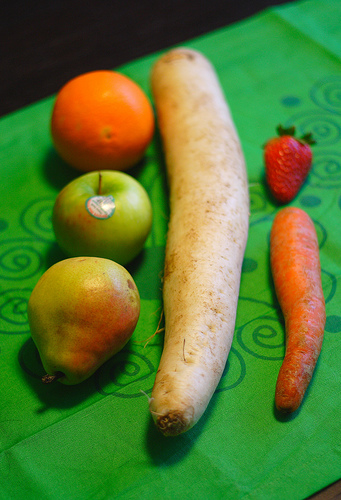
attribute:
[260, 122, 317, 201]
strawberry — red, ripe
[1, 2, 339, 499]
cloth — designed, green, light green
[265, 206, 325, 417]
carrot — orange, crooked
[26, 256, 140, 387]
pear — green, red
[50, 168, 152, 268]
apple — round, green, medium, red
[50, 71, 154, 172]
orange — bright orange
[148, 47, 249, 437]
parsnip — long, white, dirty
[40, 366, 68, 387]
stem — dark brown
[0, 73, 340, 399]
design — circular, dark green, swirled, decorative, green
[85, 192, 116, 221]
label — white, round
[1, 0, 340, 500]
table — wood, dark, brown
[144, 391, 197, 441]
roots — tiny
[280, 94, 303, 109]
dot — green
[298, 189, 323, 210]
dot — green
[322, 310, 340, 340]
dot — green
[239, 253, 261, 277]
dot — green